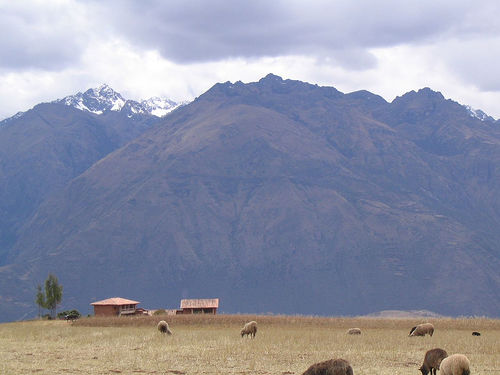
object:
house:
[177, 298, 219, 314]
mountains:
[0, 72, 499, 318]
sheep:
[304, 354, 364, 375]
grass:
[3, 308, 500, 374]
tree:
[33, 274, 64, 321]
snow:
[55, 79, 181, 111]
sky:
[0, 0, 499, 110]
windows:
[122, 305, 129, 311]